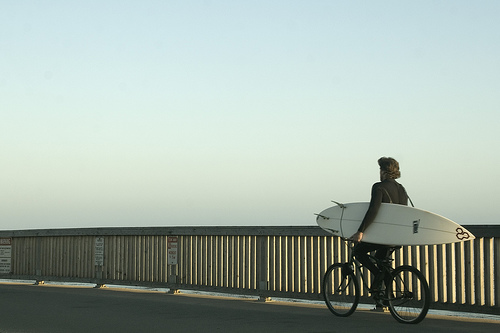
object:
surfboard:
[311, 202, 476, 243]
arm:
[358, 183, 383, 233]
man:
[349, 157, 408, 309]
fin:
[332, 200, 348, 210]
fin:
[313, 212, 329, 221]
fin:
[326, 227, 340, 235]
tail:
[316, 202, 346, 240]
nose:
[456, 221, 476, 246]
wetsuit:
[351, 181, 409, 296]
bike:
[322, 240, 432, 324]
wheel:
[322, 262, 360, 317]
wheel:
[385, 264, 431, 326]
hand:
[349, 231, 362, 245]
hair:
[378, 157, 401, 182]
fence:
[0, 225, 499, 316]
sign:
[165, 235, 180, 266]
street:
[1, 291, 500, 332]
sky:
[1, 1, 500, 230]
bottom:
[316, 202, 476, 246]